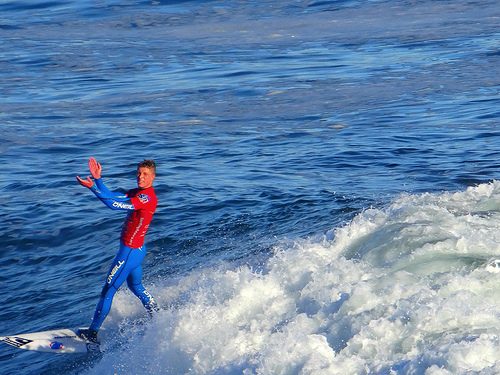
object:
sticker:
[46, 339, 65, 349]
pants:
[74, 244, 159, 338]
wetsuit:
[85, 175, 160, 336]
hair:
[134, 159, 157, 191]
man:
[66, 139, 193, 299]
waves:
[199, 171, 456, 336]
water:
[3, 6, 498, 369]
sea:
[2, 0, 497, 374]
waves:
[360, 91, 446, 145]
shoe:
[73, 321, 102, 345]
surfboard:
[0, 326, 119, 355]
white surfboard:
[0, 322, 136, 355]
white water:
[279, 176, 411, 299]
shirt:
[82, 172, 162, 255]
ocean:
[1, 5, 495, 373]